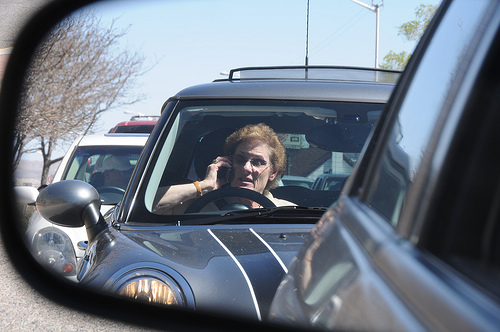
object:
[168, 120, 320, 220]
person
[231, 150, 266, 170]
glasses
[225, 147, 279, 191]
face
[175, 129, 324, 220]
person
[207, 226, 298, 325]
stripe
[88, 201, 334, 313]
hood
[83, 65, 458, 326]
car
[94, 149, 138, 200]
person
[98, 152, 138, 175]
hat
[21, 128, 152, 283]
car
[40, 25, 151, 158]
branches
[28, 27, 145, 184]
tree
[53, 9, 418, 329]
mirror